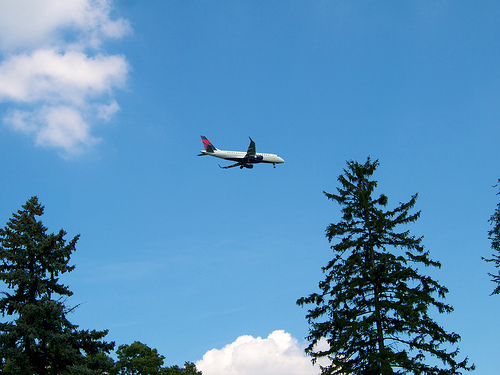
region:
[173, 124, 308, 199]
a white airplane in the sky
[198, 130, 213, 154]
blue and red on the tail fin of a plane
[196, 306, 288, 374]
a billowing white cloud in the sky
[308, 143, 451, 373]
a tall sparse pine tree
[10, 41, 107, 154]
wispy sections of a white cloud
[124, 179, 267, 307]
a light blue sky between two clouds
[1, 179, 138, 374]
a slightly bent green pine tree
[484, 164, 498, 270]
a thin edge of a pine tree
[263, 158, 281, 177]
protruding landing wheels on a plane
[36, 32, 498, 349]
an airplane flying over trees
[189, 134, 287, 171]
passenger plane in sky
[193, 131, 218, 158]
tail of passenger plane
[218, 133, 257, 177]
wings of passenger plane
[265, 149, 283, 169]
nose of passenger plane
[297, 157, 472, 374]
tall tree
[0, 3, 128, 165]
white cloud in sky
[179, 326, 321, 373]
puffy white cloud in sky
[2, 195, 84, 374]
tall green pine tree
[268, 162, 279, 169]
wheels of passenger plane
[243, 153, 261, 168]
two engines of passenger plane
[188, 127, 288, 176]
large jet in the sky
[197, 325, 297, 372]
white, puffy cloud in the sky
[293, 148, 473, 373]
tall green pine tree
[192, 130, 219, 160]
tail section of jet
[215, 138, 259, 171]
wing section of jet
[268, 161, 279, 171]
landing gear underneath jet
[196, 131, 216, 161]
tail of jet painted red and blue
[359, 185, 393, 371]
main trunk of pine tree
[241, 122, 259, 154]
rudder on wing of jet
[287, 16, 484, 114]
blue sky with no clouds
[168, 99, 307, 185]
airplane flying through the sky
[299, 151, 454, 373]
tall pine tree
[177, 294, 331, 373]
white billowy cloud in the sky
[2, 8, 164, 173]
white whispy clouds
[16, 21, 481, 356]
dark and light blue sky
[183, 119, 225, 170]
red and blue tail plane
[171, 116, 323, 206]
white plane with blue and red colors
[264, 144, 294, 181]
thick white nose of a plane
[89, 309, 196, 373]
top of a green tree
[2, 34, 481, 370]
airplane flying over trees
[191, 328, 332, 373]
only white fluffy cloud in the sky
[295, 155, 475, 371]
sparse pine tree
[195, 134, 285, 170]
large passenger plane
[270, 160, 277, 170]
plane's retractable wheels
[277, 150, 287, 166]
nose of the plane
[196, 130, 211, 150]
red and blue tail of plane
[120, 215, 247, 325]
patch of blue sky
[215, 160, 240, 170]
left wing of plane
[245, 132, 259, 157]
right wing